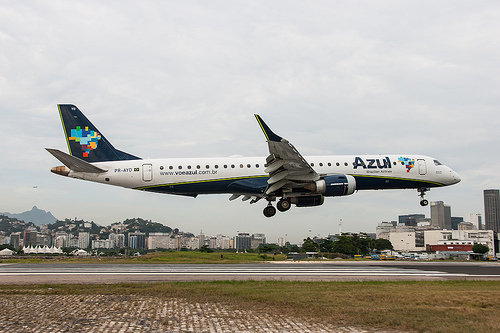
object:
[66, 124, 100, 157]
decal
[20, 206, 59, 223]
mountain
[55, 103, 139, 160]
tail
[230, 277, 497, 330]
grass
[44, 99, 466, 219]
airplane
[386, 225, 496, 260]
building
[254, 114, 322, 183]
wing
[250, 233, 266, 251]
building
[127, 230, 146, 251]
building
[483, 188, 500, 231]
building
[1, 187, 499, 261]
city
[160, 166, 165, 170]
window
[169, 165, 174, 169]
window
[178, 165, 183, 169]
window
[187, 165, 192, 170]
window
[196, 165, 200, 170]
window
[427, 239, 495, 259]
building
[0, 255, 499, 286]
tarmac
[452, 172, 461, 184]
nose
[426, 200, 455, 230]
building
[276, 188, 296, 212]
gear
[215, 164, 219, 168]
window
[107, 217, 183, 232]
hill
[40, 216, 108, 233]
hill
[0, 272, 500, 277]
lines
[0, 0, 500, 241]
air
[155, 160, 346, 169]
row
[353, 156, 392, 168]
company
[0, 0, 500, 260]
background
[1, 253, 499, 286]
landing